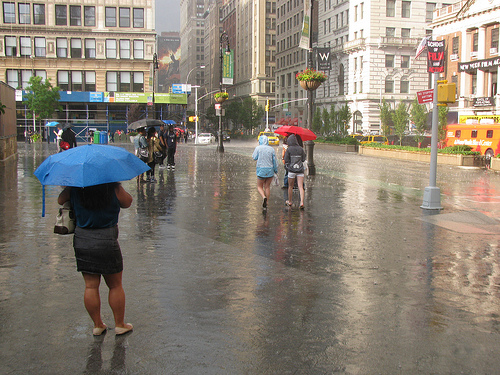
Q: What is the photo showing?
A: It is showing a sidewalk.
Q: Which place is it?
A: It is a sidewalk.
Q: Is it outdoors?
A: Yes, it is outdoors.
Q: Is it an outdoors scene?
A: Yes, it is outdoors.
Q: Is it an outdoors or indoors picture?
A: It is outdoors.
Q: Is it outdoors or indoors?
A: It is outdoors.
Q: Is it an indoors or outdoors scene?
A: It is outdoors.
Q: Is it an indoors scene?
A: No, it is outdoors.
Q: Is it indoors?
A: No, it is outdoors.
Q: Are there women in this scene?
A: Yes, there is a woman.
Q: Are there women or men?
A: Yes, there is a woman.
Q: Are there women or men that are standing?
A: Yes, the woman is standing.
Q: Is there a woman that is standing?
A: Yes, there is a woman that is standing.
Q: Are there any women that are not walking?
A: Yes, there is a woman that is standing.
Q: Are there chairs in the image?
A: No, there are no chairs.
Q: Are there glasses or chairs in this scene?
A: No, there are no chairs or glasses.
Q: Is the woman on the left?
A: Yes, the woman is on the left of the image.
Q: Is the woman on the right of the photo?
A: No, the woman is on the left of the image.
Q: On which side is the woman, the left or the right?
A: The woman is on the left of the image.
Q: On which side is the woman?
A: The woman is on the left of the image.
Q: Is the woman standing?
A: Yes, the woman is standing.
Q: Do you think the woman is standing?
A: Yes, the woman is standing.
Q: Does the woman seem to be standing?
A: Yes, the woman is standing.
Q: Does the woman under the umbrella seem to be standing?
A: Yes, the woman is standing.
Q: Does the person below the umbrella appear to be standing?
A: Yes, the woman is standing.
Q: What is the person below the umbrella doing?
A: The woman is standing.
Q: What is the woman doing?
A: The woman is standing.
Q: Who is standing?
A: The woman is standing.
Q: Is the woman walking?
A: No, the woman is standing.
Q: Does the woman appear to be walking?
A: No, the woman is standing.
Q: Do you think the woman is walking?
A: No, the woman is standing.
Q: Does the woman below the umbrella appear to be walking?
A: No, the woman is standing.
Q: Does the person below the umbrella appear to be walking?
A: No, the woman is standing.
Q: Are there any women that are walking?
A: No, there is a woman but she is standing.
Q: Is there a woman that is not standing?
A: No, there is a woman but she is standing.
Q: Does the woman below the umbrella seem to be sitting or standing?
A: The woman is standing.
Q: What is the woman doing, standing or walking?
A: The woman is standing.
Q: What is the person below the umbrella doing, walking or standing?
A: The woman is standing.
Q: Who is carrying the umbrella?
A: The woman is carrying the umbrella.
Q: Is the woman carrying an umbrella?
A: Yes, the woman is carrying an umbrella.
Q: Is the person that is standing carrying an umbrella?
A: Yes, the woman is carrying an umbrella.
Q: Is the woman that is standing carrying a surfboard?
A: No, the woman is carrying an umbrella.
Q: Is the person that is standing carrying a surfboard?
A: No, the woman is carrying an umbrella.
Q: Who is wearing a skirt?
A: The woman is wearing a skirt.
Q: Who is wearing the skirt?
A: The woman is wearing a skirt.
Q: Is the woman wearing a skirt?
A: Yes, the woman is wearing a skirt.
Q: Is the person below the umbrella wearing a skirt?
A: Yes, the woman is wearing a skirt.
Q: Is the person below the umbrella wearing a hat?
A: No, the woman is wearing a skirt.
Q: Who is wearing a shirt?
A: The woman is wearing a shirt.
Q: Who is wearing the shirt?
A: The woman is wearing a shirt.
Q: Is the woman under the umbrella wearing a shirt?
A: Yes, the woman is wearing a shirt.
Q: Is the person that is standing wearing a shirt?
A: Yes, the woman is wearing a shirt.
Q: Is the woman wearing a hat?
A: No, the woman is wearing a shirt.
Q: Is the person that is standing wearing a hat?
A: No, the woman is wearing a shirt.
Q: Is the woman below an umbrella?
A: Yes, the woman is below an umbrella.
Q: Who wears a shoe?
A: The woman wears a shoe.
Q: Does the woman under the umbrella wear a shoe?
A: Yes, the woman wears a shoe.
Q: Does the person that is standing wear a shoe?
A: Yes, the woman wears a shoe.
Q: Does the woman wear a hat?
A: No, the woman wears a shoe.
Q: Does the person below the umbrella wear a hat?
A: No, the woman wears a shoe.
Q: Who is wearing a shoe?
A: The woman is wearing a shoe.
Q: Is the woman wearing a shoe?
A: Yes, the woman is wearing a shoe.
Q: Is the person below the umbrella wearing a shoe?
A: Yes, the woman is wearing a shoe.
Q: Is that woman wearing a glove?
A: No, the woman is wearing a shoe.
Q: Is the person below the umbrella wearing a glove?
A: No, the woman is wearing a shoe.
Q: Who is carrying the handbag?
A: The woman is carrying the handbag.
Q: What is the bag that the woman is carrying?
A: The bag is a handbag.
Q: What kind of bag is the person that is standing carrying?
A: The woman is carrying a handbag.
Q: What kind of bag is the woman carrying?
A: The woman is carrying a handbag.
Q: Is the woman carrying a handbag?
A: Yes, the woman is carrying a handbag.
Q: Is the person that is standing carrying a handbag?
A: Yes, the woman is carrying a handbag.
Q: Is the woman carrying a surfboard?
A: No, the woman is carrying a handbag.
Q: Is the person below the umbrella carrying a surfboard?
A: No, the woman is carrying a handbag.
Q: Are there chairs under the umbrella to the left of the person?
A: No, there is a woman under the umbrella.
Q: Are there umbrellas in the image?
A: Yes, there is an umbrella.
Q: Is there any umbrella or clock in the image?
A: Yes, there is an umbrella.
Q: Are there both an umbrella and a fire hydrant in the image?
A: No, there is an umbrella but no fire hydrants.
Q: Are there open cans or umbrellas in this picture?
A: Yes, there is an open umbrella.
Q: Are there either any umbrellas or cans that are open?
A: Yes, the umbrella is open.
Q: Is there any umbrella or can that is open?
A: Yes, the umbrella is open.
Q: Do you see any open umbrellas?
A: Yes, there is an open umbrella.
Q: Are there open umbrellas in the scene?
A: Yes, there is an open umbrella.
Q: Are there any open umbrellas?
A: Yes, there is an open umbrella.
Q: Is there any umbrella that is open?
A: Yes, there is an umbrella that is open.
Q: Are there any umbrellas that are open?
A: Yes, there is an umbrella that is open.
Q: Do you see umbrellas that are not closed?
A: Yes, there is a open umbrella.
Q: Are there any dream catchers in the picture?
A: No, there are no dream catchers.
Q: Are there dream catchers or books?
A: No, there are no dream catchers or books.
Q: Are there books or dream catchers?
A: No, there are no dream catchers or books.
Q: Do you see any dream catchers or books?
A: No, there are no dream catchers or books.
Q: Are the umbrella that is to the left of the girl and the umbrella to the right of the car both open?
A: Yes, both the umbrella and the umbrella are open.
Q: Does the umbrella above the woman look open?
A: Yes, the umbrella is open.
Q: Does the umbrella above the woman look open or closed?
A: The umbrella is open.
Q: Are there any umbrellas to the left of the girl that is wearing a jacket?
A: Yes, there is an umbrella to the left of the girl.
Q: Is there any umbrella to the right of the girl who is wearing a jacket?
A: No, the umbrella is to the left of the girl.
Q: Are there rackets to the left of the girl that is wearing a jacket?
A: No, there is an umbrella to the left of the girl.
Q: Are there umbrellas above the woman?
A: Yes, there is an umbrella above the woman.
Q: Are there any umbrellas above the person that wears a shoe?
A: Yes, there is an umbrella above the woman.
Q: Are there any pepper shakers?
A: No, there are no pepper shakers.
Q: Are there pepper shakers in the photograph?
A: No, there are no pepper shakers.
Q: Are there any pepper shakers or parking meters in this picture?
A: No, there are no pepper shakers or parking meters.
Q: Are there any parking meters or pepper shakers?
A: No, there are no pepper shakers or parking meters.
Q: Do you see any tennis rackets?
A: No, there are no tennis rackets.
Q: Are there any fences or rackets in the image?
A: No, there are no rackets or fences.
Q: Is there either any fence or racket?
A: No, there are no rackets or fences.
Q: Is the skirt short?
A: Yes, the skirt is short.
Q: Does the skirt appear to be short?
A: Yes, the skirt is short.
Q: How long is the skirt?
A: The skirt is short.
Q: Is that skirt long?
A: No, the skirt is short.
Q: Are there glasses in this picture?
A: No, there are no glasses.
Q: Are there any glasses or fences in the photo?
A: No, there are no glasses or fences.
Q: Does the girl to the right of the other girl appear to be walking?
A: Yes, the girl is walking.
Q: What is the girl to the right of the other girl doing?
A: The girl is walking.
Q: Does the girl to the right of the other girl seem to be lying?
A: No, the girl is walking.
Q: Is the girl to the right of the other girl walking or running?
A: The girl is walking.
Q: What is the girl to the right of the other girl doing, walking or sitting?
A: The girl is walking.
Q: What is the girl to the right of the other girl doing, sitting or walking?
A: The girl is walking.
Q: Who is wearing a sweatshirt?
A: The girl is wearing a sweatshirt.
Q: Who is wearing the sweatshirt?
A: The girl is wearing a sweatshirt.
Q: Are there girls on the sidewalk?
A: Yes, there is a girl on the sidewalk.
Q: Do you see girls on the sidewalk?
A: Yes, there is a girl on the sidewalk.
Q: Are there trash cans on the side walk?
A: No, there is a girl on the side walk.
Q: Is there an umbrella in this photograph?
A: Yes, there is an umbrella.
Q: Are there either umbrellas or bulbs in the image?
A: Yes, there is an umbrella.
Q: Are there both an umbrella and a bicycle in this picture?
A: No, there is an umbrella but no bicycles.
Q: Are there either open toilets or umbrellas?
A: Yes, there is an open umbrella.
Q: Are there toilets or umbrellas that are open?
A: Yes, the umbrella is open.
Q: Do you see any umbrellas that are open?
A: Yes, there is an open umbrella.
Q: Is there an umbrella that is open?
A: Yes, there is an umbrella that is open.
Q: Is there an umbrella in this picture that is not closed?
A: Yes, there is a open umbrella.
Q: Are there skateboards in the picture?
A: No, there are no skateboards.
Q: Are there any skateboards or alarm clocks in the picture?
A: No, there are no skateboards or alarm clocks.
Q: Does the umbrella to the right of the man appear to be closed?
A: No, the umbrella is open.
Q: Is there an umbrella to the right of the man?
A: Yes, there is an umbrella to the right of the man.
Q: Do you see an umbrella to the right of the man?
A: Yes, there is an umbrella to the right of the man.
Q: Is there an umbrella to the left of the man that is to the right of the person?
A: No, the umbrella is to the right of the man.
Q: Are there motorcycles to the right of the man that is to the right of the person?
A: No, there is an umbrella to the right of the man.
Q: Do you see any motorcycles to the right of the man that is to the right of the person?
A: No, there is an umbrella to the right of the man.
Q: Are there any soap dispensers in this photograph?
A: No, there are no soap dispensers.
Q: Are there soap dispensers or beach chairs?
A: No, there are no soap dispensers or beach chairs.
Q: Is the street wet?
A: Yes, the street is wet.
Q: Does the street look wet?
A: Yes, the street is wet.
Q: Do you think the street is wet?
A: Yes, the street is wet.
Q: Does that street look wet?
A: Yes, the street is wet.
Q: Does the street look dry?
A: No, the street is wet.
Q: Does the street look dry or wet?
A: The street is wet.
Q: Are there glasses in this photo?
A: No, there are no glasses.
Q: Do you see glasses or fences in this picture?
A: No, there are no glasses or fences.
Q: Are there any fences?
A: No, there are no fences.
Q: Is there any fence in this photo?
A: No, there are no fences.